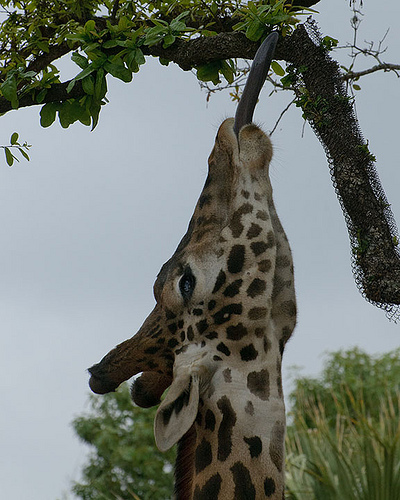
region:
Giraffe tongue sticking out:
[230, 31, 279, 129]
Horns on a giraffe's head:
[86, 304, 178, 409]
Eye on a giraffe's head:
[176, 263, 195, 304]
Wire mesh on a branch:
[281, 15, 399, 323]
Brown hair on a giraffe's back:
[175, 425, 195, 498]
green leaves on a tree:
[36, 13, 194, 133]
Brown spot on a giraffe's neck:
[216, 396, 238, 460]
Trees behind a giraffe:
[283, 344, 399, 497]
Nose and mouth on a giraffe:
[202, 117, 273, 174]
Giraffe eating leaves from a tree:
[81, 31, 301, 444]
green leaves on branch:
[0, 0, 301, 162]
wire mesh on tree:
[283, 16, 399, 315]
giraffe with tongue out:
[88, 30, 297, 498]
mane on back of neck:
[172, 426, 198, 498]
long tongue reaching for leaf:
[218, 6, 279, 163]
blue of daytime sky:
[1, 2, 395, 494]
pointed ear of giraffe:
[153, 358, 205, 450]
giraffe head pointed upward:
[89, 116, 300, 498]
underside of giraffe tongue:
[235, 31, 280, 131]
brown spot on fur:
[245, 366, 272, 400]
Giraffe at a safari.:
[11, 5, 385, 484]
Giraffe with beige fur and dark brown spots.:
[46, 91, 347, 477]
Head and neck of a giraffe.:
[58, 102, 303, 483]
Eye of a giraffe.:
[134, 241, 220, 316]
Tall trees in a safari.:
[65, 337, 398, 499]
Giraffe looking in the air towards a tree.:
[11, 5, 387, 477]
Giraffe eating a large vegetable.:
[184, 22, 322, 210]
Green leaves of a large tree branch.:
[0, 0, 323, 121]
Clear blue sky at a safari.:
[15, 105, 393, 450]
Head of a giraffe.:
[45, 93, 353, 451]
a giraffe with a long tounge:
[102, 29, 322, 427]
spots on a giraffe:
[145, 215, 271, 438]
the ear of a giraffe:
[153, 348, 218, 456]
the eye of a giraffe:
[153, 255, 209, 320]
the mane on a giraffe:
[168, 418, 200, 499]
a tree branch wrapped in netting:
[296, 54, 396, 299]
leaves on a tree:
[41, 14, 190, 119]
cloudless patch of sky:
[113, 116, 186, 212]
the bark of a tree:
[189, 35, 246, 59]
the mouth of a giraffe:
[200, 30, 294, 236]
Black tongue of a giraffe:
[232, 26, 278, 132]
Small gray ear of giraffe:
[152, 378, 198, 454]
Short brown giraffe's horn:
[87, 329, 167, 410]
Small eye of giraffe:
[181, 269, 195, 303]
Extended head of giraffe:
[87, 119, 297, 426]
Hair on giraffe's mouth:
[253, 121, 279, 165]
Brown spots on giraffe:
[128, 167, 300, 499]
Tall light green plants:
[281, 351, 399, 499]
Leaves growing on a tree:
[0, 0, 309, 140]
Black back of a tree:
[171, 29, 399, 300]